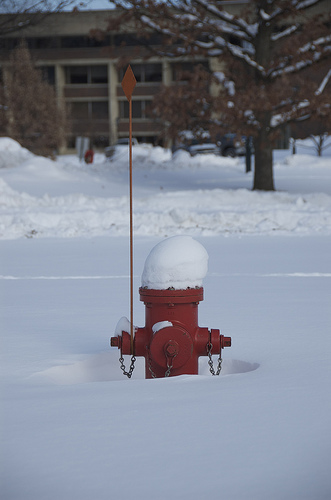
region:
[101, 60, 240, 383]
a fire hydrant on snow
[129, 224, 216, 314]
snow on a fire hydrant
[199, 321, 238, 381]
chain in fire hydrant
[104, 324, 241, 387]
three chains in fire hydrant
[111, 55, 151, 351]
a pole on side of hydrant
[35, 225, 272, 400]
snow around fire hydrant is sunken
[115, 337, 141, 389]
chain on left side of fire hydrant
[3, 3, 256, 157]
building on back a tree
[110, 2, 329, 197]
a tree in front a building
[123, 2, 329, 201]
some snow on branches of tree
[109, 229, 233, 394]
A red fire hydrant half burried in snow.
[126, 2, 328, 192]
Large tree in the right background.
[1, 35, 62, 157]
Smaller tree in the left background.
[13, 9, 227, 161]
Building in the center of the background.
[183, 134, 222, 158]
White truck in building parking lot.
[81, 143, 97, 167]
Person in background.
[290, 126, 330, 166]
smaller trees in far right background.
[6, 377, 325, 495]
Clean white undisturbed snow.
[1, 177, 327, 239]
Disheveled snow in the background.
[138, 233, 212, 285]
Snow on top of fire hydrant.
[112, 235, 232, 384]
A red fire hydrant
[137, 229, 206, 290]
Snow on top of the hydrant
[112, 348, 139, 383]
chain for the hydrant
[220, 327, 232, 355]
The valvue to release water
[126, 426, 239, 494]
The undisturbed snow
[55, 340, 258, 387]
Ditch around the hydrant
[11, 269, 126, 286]
a line in the snow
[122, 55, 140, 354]
an orange marker on the hydrant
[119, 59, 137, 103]
an orange diamond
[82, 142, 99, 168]
a person in a red shirt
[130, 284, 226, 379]
red fire hydrant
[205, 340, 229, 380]
fire hydrant chain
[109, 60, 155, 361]
red or orange flag attached to fire hydrant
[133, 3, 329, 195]
large tree with orange dead leaves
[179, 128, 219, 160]
silver or grey vehicle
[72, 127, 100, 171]
white sign with metal pole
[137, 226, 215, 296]
small white snow mound on top of fire hydrant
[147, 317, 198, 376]
red fire hydrant cap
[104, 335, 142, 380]
second fire hydrant chain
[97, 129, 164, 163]
white truck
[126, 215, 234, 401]
small red fire hydrant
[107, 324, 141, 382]
first fire hydrant chain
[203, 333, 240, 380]
second fire hydrant chain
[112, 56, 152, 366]
orange fire hydrant flag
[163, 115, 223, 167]
silver or grey vehicle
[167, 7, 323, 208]
large tree with orange leaves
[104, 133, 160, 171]
white truck behind snow pile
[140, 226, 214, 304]
small snow mound on fire hydrant